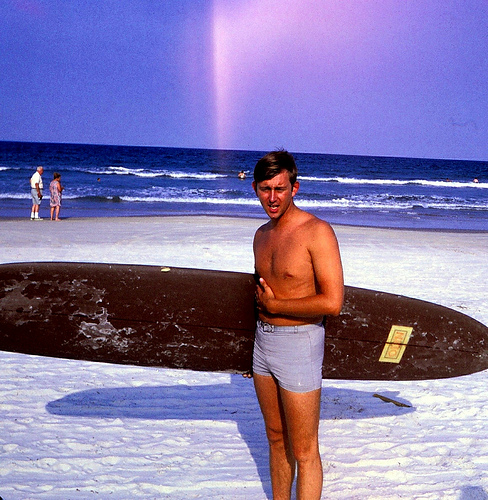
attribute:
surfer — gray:
[187, 140, 380, 395]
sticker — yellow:
[372, 311, 408, 372]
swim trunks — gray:
[253, 317, 326, 391]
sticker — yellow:
[376, 324, 412, 365]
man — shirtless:
[246, 147, 344, 498]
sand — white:
[0, 219, 488, 498]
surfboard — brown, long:
[4, 264, 486, 378]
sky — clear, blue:
[5, 3, 475, 164]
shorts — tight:
[248, 320, 324, 386]